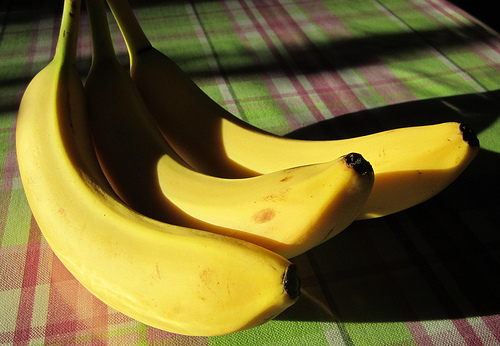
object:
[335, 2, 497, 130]
stripes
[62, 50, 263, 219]
shadow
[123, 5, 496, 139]
table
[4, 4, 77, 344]
table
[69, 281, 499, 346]
table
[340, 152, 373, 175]
tip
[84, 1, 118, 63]
stems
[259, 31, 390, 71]
table cloth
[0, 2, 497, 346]
table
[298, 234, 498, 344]
table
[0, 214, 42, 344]
stripes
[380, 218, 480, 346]
stripes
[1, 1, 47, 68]
stripes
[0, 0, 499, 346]
plaid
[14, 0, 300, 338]
banana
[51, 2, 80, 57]
stem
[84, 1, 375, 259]
banana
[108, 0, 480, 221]
banana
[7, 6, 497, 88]
table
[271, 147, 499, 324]
shadow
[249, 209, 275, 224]
scratch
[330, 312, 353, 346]
stripes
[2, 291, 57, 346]
tablecloth